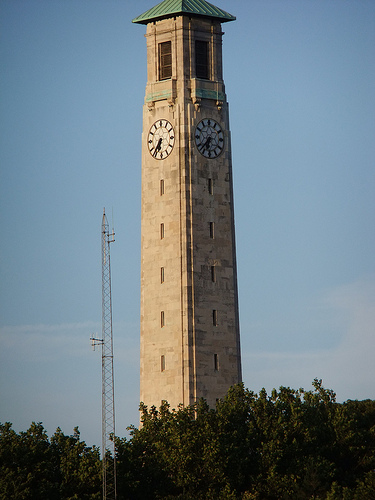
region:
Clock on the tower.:
[182, 92, 252, 183]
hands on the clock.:
[187, 123, 208, 158]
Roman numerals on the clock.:
[173, 112, 248, 177]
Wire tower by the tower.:
[66, 184, 154, 366]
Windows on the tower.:
[190, 239, 247, 312]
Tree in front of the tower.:
[117, 359, 307, 497]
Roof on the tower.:
[137, 0, 250, 53]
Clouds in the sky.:
[28, 296, 127, 383]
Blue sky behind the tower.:
[32, 307, 245, 454]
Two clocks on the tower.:
[137, 97, 291, 196]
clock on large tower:
[146, 117, 177, 159]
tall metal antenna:
[78, 198, 126, 498]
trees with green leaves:
[165, 420, 287, 467]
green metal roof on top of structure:
[127, 0, 232, 21]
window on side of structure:
[147, 174, 169, 201]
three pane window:
[153, 39, 172, 78]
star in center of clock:
[140, 118, 175, 160]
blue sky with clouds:
[255, 322, 350, 372]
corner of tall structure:
[172, 78, 196, 398]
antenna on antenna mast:
[106, 204, 118, 245]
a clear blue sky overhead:
[245, 34, 355, 329]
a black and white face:
[194, 116, 227, 159]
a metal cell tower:
[94, 203, 114, 496]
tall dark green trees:
[146, 400, 338, 480]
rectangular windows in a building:
[201, 172, 227, 384]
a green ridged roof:
[135, 2, 240, 15]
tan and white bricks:
[178, 196, 199, 281]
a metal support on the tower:
[88, 334, 99, 350]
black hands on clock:
[154, 138, 164, 149]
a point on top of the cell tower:
[98, 203, 109, 216]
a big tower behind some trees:
[0, 5, 369, 487]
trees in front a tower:
[6, 382, 373, 498]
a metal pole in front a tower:
[88, 196, 122, 498]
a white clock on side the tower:
[142, 117, 178, 163]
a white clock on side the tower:
[188, 112, 230, 165]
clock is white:
[143, 119, 177, 162]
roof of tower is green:
[132, 2, 240, 26]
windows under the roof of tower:
[138, 31, 222, 83]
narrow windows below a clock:
[153, 172, 169, 373]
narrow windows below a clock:
[199, 167, 232, 379]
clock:
[145, 111, 187, 166]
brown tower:
[155, 3, 236, 394]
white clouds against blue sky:
[5, 8, 48, 76]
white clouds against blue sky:
[8, 91, 42, 139]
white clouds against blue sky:
[25, 161, 51, 239]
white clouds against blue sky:
[8, 250, 46, 311]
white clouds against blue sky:
[26, 308, 67, 372]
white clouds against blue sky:
[238, 61, 300, 138]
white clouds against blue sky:
[291, 167, 355, 288]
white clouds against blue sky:
[248, 142, 274, 225]